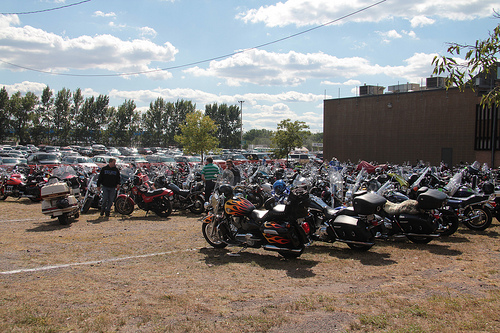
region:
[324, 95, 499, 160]
The brown building on the right.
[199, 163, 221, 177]
The green shirt the man is wearing.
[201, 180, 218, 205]
The black pants the man is wearing.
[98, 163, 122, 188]
The black sweatshirt the man is wearing.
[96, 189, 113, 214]
The blue jeans the man is wearing.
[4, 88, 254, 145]
The trees in the distance.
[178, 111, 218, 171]
The tree in the middle of the parking lot.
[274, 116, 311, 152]
The green tree in the middle of the parking lot near the right.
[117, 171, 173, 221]
The red motorcycle next to the man in the sweater.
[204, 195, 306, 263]
The motorcycle in the back row with flames painted on it.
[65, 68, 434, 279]
these are motorcycles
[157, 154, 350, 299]
the motorcycles are parked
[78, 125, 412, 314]
there are lots of motorcycles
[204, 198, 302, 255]
the motorcycle has flames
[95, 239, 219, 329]
the field is bare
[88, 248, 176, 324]
the field is dry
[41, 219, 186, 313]
the field is light brown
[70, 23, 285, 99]
the clouds are white and fluffy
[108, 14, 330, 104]
the sky is partly cloud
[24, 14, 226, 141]
these are power lines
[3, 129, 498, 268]
motorcycles parked on a field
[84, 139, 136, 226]
man wearing black clothes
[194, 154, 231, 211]
person has green top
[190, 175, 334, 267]
motorcycle is color black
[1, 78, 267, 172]
many trees behind the cars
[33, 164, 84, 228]
motorcycle has a white box on back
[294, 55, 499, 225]
motorcycles in front a red building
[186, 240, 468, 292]
shadow on the soil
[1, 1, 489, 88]
sky with white clouds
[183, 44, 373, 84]
a white cloud on blue sky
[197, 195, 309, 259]
the bike is parked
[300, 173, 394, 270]
the bike is parked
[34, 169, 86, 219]
the bike is parked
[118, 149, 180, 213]
the bike is parked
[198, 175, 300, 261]
flame motorcycle on ground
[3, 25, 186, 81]
cloud in blue sky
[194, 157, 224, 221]
man in striped shirt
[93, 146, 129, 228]
man in black shirt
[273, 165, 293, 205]
blue helmet on motorcycle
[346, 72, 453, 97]
air conditioning units atop building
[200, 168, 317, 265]
the motorcycle is parked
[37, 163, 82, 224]
the motorcycle is parked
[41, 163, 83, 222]
the motorcycle is beige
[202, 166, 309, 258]
the motorcycle has painted flames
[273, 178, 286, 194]
the helmet is blue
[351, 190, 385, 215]
the helmet case is black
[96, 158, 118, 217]
the man is standing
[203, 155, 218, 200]
the man is standing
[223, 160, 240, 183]
the man is standing